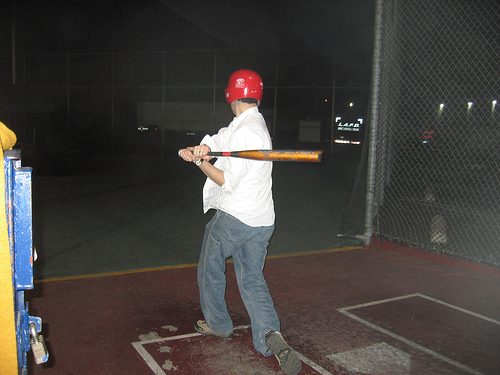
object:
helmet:
[225, 68, 264, 108]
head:
[225, 66, 264, 112]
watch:
[191, 155, 203, 169]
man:
[179, 68, 307, 374]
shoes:
[192, 319, 236, 339]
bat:
[185, 142, 327, 164]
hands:
[185, 144, 213, 160]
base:
[324, 340, 413, 374]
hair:
[235, 95, 260, 106]